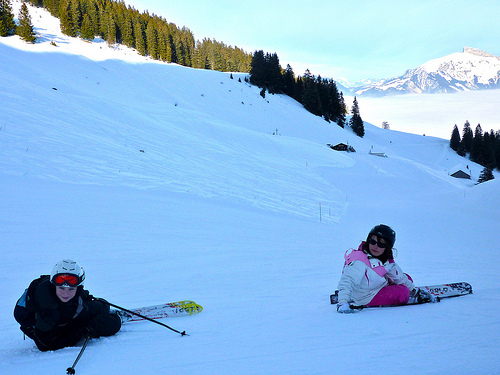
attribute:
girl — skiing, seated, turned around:
[327, 218, 484, 316]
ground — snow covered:
[278, 195, 401, 209]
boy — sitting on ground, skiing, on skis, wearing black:
[13, 281, 143, 328]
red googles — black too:
[48, 273, 84, 284]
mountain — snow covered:
[378, 38, 496, 93]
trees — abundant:
[105, 6, 231, 66]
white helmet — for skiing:
[36, 260, 95, 273]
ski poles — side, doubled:
[111, 293, 189, 348]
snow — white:
[106, 74, 164, 93]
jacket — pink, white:
[354, 270, 377, 292]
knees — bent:
[394, 284, 416, 303]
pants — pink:
[364, 284, 424, 306]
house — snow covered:
[440, 148, 476, 188]